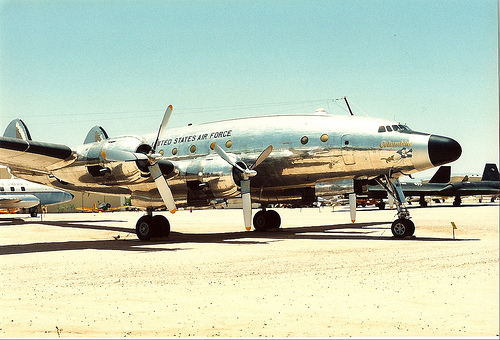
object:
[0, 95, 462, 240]
plane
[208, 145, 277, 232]
propeller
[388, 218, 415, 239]
wheel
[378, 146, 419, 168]
graphic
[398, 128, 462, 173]
nose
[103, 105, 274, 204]
engine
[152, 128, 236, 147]
writing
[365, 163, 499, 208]
jet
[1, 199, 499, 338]
runway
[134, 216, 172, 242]
back wheel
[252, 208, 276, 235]
back wheel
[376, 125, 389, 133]
window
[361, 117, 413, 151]
cockpit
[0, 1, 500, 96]
sky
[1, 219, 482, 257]
shadow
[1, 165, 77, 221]
airplane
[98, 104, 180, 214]
propeller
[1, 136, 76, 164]
edge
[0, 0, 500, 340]
picture